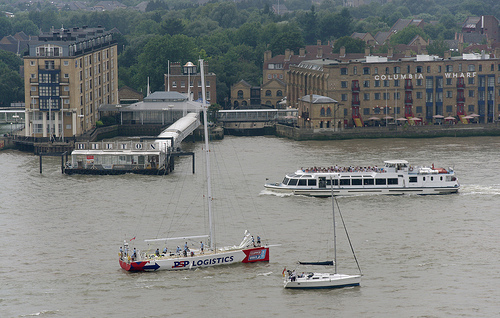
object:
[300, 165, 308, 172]
people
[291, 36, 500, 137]
building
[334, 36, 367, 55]
tree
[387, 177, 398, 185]
window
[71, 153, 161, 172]
patio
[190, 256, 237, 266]
logistics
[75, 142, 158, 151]
sign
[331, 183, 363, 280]
sail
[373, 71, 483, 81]
sign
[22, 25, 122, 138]
hotel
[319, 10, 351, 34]
tree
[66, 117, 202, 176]
docking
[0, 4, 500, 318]
area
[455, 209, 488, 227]
wave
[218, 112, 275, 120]
walk way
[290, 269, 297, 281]
shipmate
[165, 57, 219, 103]
building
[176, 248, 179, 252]
shirt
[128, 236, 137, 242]
flag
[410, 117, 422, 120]
umbrella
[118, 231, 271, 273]
boat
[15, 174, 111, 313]
water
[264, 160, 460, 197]
boat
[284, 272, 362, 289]
boat